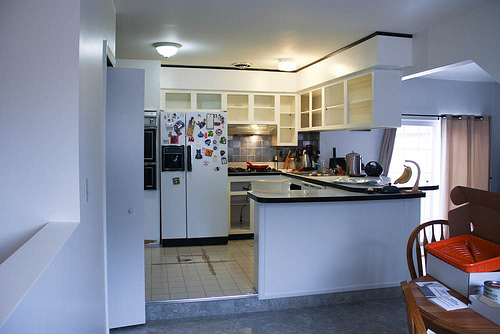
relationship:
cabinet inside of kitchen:
[117, 59, 401, 146] [108, 50, 420, 305]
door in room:
[98, 37, 166, 330] [0, 2, 496, 325]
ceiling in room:
[136, 15, 438, 63] [18, 8, 481, 294]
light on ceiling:
[152, 42, 183, 60] [113, 0, 445, 70]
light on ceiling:
[273, 57, 300, 74] [115, 3, 407, 80]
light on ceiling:
[151, 40, 183, 60] [115, 3, 407, 80]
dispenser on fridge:
[153, 140, 186, 170] [152, 106, 234, 248]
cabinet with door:
[117, 59, 401, 146] [347, 71, 375, 123]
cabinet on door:
[117, 59, 401, 146] [322, 80, 348, 120]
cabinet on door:
[117, 59, 401, 146] [268, 78, 312, 137]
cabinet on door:
[117, 59, 401, 146] [275, 95, 282, 146]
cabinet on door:
[117, 59, 401, 146] [253, 93, 274, 119]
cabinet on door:
[214, 97, 254, 132] [224, 94, 249, 122]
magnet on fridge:
[164, 113, 228, 172] [154, 107, 244, 233]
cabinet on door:
[117, 59, 401, 146] [345, 75, 374, 125]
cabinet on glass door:
[117, 59, 401, 146] [298, 86, 323, 128]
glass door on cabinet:
[388, 110, 493, 255] [158, 64, 410, 151]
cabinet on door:
[117, 59, 401, 146] [191, 92, 228, 109]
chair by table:
[400, 282, 423, 330] [408, 273, 498, 328]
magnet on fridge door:
[204, 147, 213, 157] [184, 110, 227, 238]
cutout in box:
[461, 220, 479, 237] [417, 174, 499, 293]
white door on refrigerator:
[158, 110, 185, 241] [185, 109, 230, 239]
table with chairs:
[414, 268, 464, 324] [390, 207, 482, 329]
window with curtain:
[393, 110, 492, 268] [441, 108, 481, 176]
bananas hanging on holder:
[389, 165, 412, 183] [403, 157, 423, 192]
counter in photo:
[246, 163, 438, 202] [4, 4, 481, 331]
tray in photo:
[419, 228, 499, 297] [4, 4, 481, 331]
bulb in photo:
[147, 36, 184, 61] [4, 4, 481, 331]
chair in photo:
[400, 282, 425, 334] [4, 4, 481, 331]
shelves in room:
[259, 91, 342, 116] [70, 8, 484, 320]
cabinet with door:
[117, 59, 401, 146] [144, 60, 166, 104]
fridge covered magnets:
[152, 106, 234, 248] [162, 110, 227, 184]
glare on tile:
[168, 111, 221, 171] [246, 161, 427, 206]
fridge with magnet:
[159, 110, 228, 245] [205, 145, 212, 155]